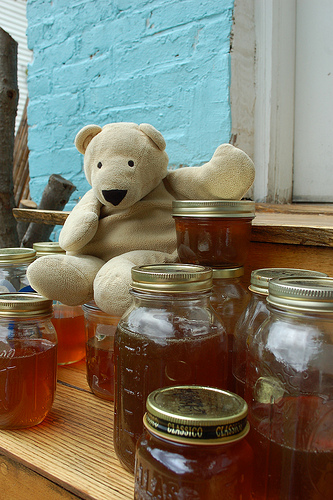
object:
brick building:
[23, 0, 333, 206]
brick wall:
[25, 0, 258, 199]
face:
[83, 140, 168, 210]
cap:
[170, 200, 257, 219]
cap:
[33, 242, 67, 256]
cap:
[0, 247, 37, 265]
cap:
[0, 292, 53, 319]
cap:
[266, 276, 333, 314]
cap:
[130, 262, 214, 295]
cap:
[208, 264, 245, 279]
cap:
[247, 267, 330, 296]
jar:
[132, 385, 255, 498]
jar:
[231, 267, 329, 402]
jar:
[209, 280, 256, 391]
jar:
[0, 247, 37, 294]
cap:
[142, 385, 250, 446]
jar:
[51, 301, 86, 366]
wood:
[251, 203, 333, 277]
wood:
[13, 207, 70, 226]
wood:
[0, 27, 20, 248]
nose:
[102, 189, 129, 207]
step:
[251, 202, 333, 279]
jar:
[84, 311, 122, 403]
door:
[253, 0, 333, 207]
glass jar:
[0, 292, 58, 431]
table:
[0, 353, 135, 500]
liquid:
[0, 342, 58, 430]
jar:
[170, 199, 256, 270]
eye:
[97, 162, 103, 170]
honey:
[174, 219, 252, 270]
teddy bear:
[26, 122, 256, 315]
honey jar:
[113, 263, 229, 475]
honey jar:
[244, 275, 333, 499]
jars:
[33, 242, 67, 260]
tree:
[0, 25, 22, 251]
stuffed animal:
[25, 120, 255, 316]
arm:
[173, 142, 255, 200]